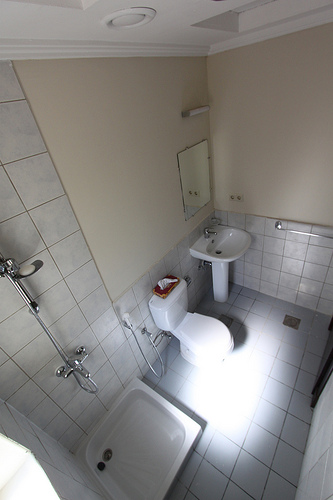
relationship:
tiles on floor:
[254, 310, 284, 351] [161, 298, 305, 409]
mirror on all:
[169, 131, 233, 224] [68, 105, 190, 266]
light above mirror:
[169, 92, 233, 126] [169, 131, 233, 224]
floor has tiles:
[161, 298, 305, 409] [254, 310, 284, 351]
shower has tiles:
[14, 211, 159, 463] [254, 310, 284, 351]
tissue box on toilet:
[149, 271, 186, 305] [136, 261, 245, 357]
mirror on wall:
[169, 131, 233, 224] [72, 85, 152, 170]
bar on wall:
[268, 207, 322, 247] [72, 85, 152, 170]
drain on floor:
[276, 306, 306, 335] [161, 298, 305, 409]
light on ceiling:
[96, 8, 157, 58] [54, 9, 223, 73]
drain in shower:
[276, 306, 306, 335] [14, 211, 159, 463]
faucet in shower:
[198, 220, 215, 243] [14, 211, 159, 463]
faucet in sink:
[198, 220, 215, 243] [187, 218, 258, 304]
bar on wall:
[268, 207, 333, 257] [72, 85, 152, 170]